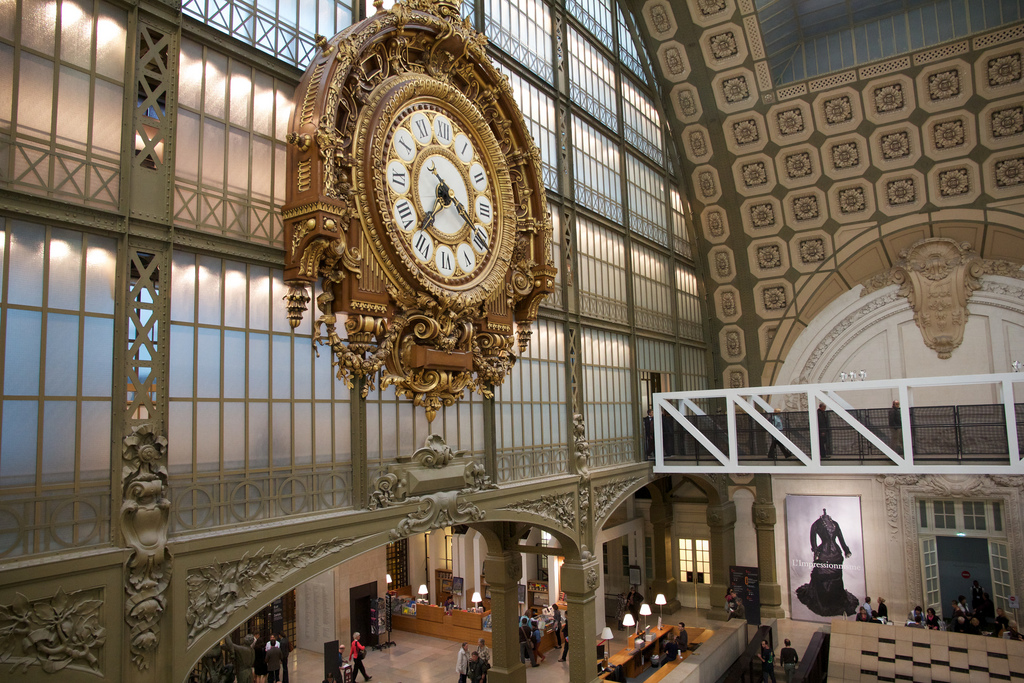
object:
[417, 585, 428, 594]
lamp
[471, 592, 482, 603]
lamp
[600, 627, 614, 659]
lamp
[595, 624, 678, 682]
desk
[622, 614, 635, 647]
lamp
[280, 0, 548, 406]
clock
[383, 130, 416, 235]
circles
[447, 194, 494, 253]
hand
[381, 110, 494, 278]
numbers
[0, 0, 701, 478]
panel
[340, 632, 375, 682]
woman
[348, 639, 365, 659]
shirt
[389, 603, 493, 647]
desk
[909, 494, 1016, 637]
door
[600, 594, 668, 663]
lamp shade